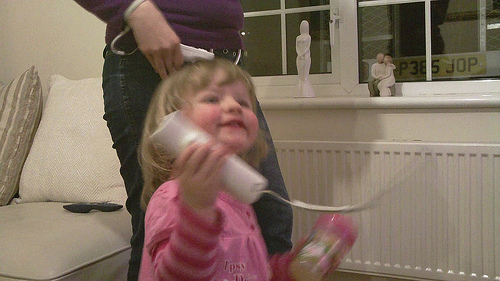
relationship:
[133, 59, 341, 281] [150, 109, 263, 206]
blond girl holding controller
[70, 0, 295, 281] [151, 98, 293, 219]
father holding controller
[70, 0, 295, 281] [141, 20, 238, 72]
father holding controller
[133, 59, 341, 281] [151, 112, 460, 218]
blond girl playing video games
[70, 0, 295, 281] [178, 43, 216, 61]
father playing controller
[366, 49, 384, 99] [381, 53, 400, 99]
man holding woman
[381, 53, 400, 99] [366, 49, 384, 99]
woman holding man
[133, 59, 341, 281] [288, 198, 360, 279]
blond girl holding sippy cup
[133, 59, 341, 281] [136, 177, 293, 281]
blond girl wearing pink shirt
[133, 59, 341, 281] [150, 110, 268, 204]
blond girl holding controller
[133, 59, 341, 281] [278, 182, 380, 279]
blond girl holding cup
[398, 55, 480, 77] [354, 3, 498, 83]
numbers in window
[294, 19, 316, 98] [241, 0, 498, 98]
figurine by window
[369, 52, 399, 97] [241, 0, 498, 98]
figurine by window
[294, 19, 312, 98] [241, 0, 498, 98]
figurine by window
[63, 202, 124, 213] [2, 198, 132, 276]
remote on couch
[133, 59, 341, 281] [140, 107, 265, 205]
blond girl holding remote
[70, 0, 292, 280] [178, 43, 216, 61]
father holding controller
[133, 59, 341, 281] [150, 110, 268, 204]
blond girl playing controller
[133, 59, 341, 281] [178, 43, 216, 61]
blond girl playing controller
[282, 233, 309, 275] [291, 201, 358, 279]
hand holding cup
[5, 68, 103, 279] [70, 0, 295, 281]
couch behind father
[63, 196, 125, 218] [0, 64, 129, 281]
remote sits on couch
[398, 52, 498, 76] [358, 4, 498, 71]
sign outside window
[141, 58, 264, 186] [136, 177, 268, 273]
blond girl with pink shirt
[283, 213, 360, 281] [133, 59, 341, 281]
cup for blond girl